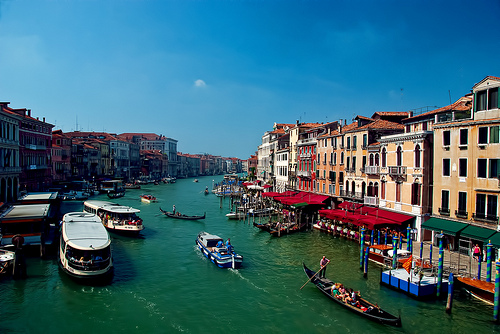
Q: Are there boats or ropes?
A: Yes, there is a boat.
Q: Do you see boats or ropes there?
A: Yes, there is a boat.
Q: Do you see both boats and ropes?
A: No, there is a boat but no ropes.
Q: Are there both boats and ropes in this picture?
A: No, there is a boat but no ropes.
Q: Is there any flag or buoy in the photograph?
A: No, there are no flags or buoys.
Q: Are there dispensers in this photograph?
A: No, there are no dispensers.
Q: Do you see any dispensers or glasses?
A: No, there are no dispensers or glasses.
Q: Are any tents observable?
A: No, there are no tents.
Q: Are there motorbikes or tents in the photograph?
A: No, there are no tents or motorbikes.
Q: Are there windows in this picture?
A: Yes, there is a window.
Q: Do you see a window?
A: Yes, there is a window.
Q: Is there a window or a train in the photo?
A: Yes, there is a window.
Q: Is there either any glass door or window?
A: Yes, there is a glass window.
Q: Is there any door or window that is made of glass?
A: Yes, the window is made of glass.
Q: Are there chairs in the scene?
A: No, there are no chairs.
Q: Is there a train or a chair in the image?
A: No, there are no chairs or trains.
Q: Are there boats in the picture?
A: Yes, there is a boat.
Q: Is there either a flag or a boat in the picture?
A: Yes, there is a boat.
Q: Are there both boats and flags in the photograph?
A: No, there is a boat but no flags.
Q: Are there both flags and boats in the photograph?
A: No, there is a boat but no flags.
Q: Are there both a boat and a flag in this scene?
A: No, there is a boat but no flags.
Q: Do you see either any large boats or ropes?
A: Yes, there is a large boat.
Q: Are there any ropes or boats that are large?
A: Yes, the boat is large.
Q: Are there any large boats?
A: Yes, there is a large boat.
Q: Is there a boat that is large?
A: Yes, there is a boat that is large.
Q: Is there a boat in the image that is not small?
A: Yes, there is a large boat.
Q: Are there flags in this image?
A: No, there are no flags.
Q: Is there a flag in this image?
A: No, there are no flags.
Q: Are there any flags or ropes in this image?
A: No, there are no flags or ropes.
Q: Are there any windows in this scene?
A: Yes, there is a window.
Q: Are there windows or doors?
A: Yes, there is a window.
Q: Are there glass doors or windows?
A: Yes, there is a glass window.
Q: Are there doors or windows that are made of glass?
A: Yes, the window is made of glass.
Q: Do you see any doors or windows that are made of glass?
A: Yes, the window is made of glass.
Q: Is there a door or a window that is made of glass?
A: Yes, the window is made of glass.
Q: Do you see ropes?
A: No, there are no ropes.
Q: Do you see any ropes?
A: No, there are no ropes.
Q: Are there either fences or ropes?
A: No, there are no ropes or fences.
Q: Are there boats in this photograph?
A: Yes, there is a boat.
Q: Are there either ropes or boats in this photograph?
A: Yes, there is a boat.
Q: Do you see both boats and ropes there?
A: No, there is a boat but no ropes.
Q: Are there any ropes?
A: No, there are no ropes.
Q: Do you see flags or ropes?
A: No, there are no ropes or flags.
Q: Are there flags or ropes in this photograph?
A: No, there are no ropes or flags.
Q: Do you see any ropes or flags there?
A: No, there are no ropes or flags.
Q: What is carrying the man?
A: The boat is carrying the man.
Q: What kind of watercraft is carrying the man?
A: The watercraft is a boat.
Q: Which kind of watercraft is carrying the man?
A: The watercraft is a boat.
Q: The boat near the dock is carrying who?
A: The boat is carrying a man.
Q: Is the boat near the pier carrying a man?
A: Yes, the boat is carrying a man.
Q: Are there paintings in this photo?
A: No, there are no paintings.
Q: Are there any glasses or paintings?
A: No, there are no paintings or glasses.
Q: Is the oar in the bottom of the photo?
A: Yes, the oar is in the bottom of the image.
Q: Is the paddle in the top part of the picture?
A: No, the paddle is in the bottom of the image.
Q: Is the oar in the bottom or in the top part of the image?
A: The oar is in the bottom of the image.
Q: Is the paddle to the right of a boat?
A: No, the paddle is to the left of a boat.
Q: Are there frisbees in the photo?
A: No, there are no frisbees.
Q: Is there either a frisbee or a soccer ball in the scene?
A: No, there are no frisbees or soccer balls.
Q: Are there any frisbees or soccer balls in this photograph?
A: No, there are no frisbees or soccer balls.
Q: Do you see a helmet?
A: No, there are no helmets.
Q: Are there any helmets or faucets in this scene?
A: No, there are no helmets or faucets.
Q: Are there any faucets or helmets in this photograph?
A: No, there are no helmets or faucets.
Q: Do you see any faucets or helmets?
A: No, there are no helmets or faucets.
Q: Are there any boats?
A: Yes, there is a boat.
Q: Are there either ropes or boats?
A: Yes, there is a boat.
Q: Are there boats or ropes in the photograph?
A: Yes, there is a boat.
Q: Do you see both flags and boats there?
A: No, there is a boat but no flags.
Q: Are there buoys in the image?
A: No, there are no buoys.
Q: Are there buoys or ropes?
A: No, there are no buoys or ropes.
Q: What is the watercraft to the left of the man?
A: The watercraft is a boat.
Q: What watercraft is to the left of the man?
A: The watercraft is a boat.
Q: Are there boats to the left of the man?
A: Yes, there is a boat to the left of the man.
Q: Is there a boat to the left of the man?
A: Yes, there is a boat to the left of the man.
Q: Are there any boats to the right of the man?
A: No, the boat is to the left of the man.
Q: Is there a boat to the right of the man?
A: No, the boat is to the left of the man.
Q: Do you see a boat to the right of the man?
A: No, the boat is to the left of the man.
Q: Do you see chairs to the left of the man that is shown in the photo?
A: No, there is a boat to the left of the man.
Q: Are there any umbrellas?
A: No, there are no umbrellas.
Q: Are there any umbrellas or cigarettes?
A: No, there are no umbrellas or cigarettes.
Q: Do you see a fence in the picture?
A: No, there are no fences.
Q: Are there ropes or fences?
A: No, there are no fences or ropes.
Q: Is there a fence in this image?
A: No, there are no fences.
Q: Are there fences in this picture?
A: No, there are no fences.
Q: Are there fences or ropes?
A: No, there are no fences or ropes.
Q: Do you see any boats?
A: Yes, there is a boat.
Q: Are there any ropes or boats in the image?
A: Yes, there is a boat.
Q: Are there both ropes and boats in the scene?
A: No, there is a boat but no ropes.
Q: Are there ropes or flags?
A: No, there are no ropes or flags.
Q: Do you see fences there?
A: No, there are no fences.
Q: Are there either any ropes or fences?
A: No, there are no fences or ropes.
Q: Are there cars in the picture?
A: No, there are no cars.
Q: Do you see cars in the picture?
A: No, there are no cars.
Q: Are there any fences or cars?
A: No, there are no cars or fences.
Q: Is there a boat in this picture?
A: Yes, there is a boat.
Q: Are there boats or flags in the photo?
A: Yes, there is a boat.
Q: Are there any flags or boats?
A: Yes, there is a boat.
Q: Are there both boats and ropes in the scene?
A: No, there is a boat but no ropes.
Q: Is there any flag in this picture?
A: No, there are no flags.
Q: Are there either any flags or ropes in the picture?
A: No, there are no flags or ropes.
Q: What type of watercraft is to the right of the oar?
A: The watercraft is a boat.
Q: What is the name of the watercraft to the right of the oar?
A: The watercraft is a boat.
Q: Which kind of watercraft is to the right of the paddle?
A: The watercraft is a boat.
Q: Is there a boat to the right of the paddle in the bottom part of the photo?
A: Yes, there is a boat to the right of the oar.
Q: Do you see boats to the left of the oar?
A: No, the boat is to the right of the oar.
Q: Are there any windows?
A: Yes, there is a window.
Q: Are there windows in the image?
A: Yes, there is a window.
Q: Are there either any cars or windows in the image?
A: Yes, there is a window.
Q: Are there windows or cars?
A: Yes, there is a window.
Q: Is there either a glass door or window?
A: Yes, there is a glass window.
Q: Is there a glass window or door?
A: Yes, there is a glass window.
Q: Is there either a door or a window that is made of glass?
A: Yes, the window is made of glass.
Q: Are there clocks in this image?
A: No, there are no clocks.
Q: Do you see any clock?
A: No, there are no clocks.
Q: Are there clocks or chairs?
A: No, there are no clocks or chairs.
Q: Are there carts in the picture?
A: No, there are no carts.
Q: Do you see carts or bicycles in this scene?
A: No, there are no carts or bicycles.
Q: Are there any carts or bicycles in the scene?
A: No, there are no carts or bicycles.